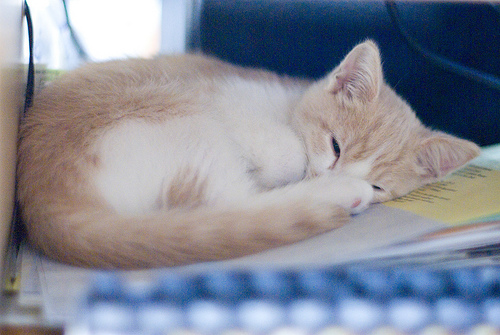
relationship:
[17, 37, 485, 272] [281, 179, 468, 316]
cat on surface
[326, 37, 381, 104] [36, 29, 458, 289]
cat ear of cat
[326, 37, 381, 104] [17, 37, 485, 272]
cat ear belonging to cat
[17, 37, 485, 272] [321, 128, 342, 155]
cat has eye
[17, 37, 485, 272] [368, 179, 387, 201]
cat has eye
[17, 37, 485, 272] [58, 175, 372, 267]
cat has tail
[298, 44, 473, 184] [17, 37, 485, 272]
head of cat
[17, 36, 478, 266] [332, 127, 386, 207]
cat with eyes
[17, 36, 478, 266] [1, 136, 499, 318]
cat laying on paper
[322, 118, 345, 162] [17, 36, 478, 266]
eye of cat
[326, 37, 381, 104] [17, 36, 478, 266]
cat ear of cat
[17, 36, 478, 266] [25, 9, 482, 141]
cat in background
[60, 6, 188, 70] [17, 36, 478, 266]
window behind cat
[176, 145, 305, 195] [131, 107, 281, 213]
fur on belly